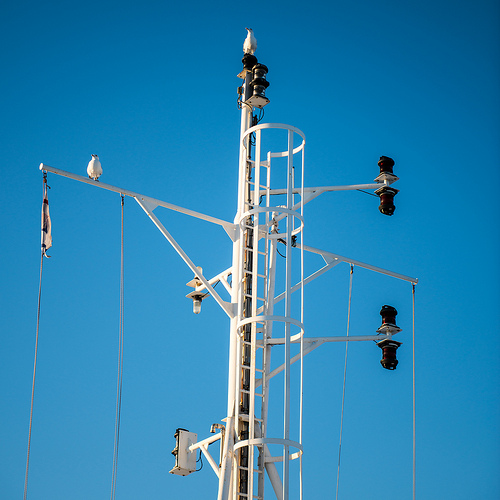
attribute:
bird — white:
[80, 152, 108, 180]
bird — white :
[85, 147, 103, 184]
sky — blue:
[15, 1, 498, 498]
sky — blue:
[273, 10, 498, 498]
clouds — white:
[48, 112, 127, 136]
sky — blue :
[8, 5, 236, 167]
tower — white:
[34, 21, 428, 498]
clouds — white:
[26, 56, 446, 178]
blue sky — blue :
[3, 0, 498, 499]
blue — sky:
[3, 397, 48, 447]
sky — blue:
[35, 45, 450, 492]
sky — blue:
[10, 29, 499, 479]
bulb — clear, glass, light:
[183, 275, 244, 340]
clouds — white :
[307, 54, 387, 99]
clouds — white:
[362, 25, 432, 108]